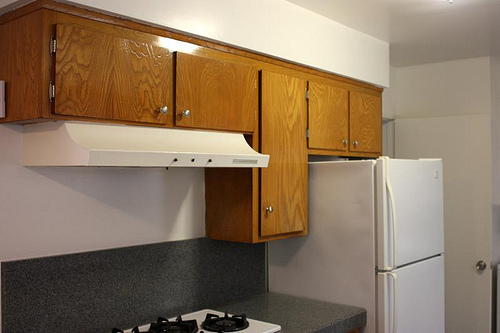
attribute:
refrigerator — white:
[263, 151, 448, 331]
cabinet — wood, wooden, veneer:
[204, 54, 311, 244]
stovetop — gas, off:
[98, 302, 286, 331]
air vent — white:
[19, 117, 273, 175]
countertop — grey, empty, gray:
[221, 285, 366, 329]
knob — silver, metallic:
[158, 103, 171, 117]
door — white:
[391, 108, 495, 332]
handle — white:
[374, 149, 402, 273]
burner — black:
[198, 307, 257, 333]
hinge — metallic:
[302, 84, 311, 104]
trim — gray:
[2, 233, 270, 332]